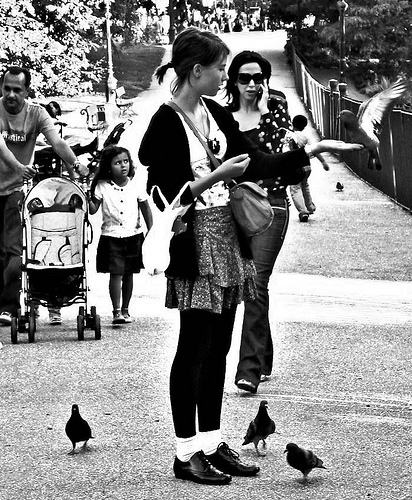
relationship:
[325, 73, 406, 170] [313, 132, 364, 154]
pigeon landing on hand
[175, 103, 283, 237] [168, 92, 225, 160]
purse has strap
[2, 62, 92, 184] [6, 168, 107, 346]
man pushing stroller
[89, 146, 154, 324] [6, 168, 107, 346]
girl walking next stroller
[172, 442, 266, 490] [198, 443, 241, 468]
shoes have black laces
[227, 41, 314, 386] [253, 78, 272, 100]
lady has cell pone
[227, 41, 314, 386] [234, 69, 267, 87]
lady wearing sunglasses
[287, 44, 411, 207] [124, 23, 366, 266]
fence runs along walkway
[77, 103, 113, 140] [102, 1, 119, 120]
bench next to post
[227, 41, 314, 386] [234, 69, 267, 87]
woman wearing sunglasses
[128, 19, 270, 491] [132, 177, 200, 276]
woman carrying bag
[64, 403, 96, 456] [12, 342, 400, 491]
birds on ground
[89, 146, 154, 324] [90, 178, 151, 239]
girl wearing shirt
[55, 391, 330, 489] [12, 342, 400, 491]
birds are on ground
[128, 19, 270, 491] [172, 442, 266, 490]
woman has black shoes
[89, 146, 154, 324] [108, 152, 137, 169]
girl looking away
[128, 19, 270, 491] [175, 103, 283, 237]
woman has a purse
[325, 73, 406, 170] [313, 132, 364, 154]
bird eating from hand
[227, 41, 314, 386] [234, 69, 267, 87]
woman has sunglasses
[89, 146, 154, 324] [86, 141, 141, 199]
girl has dark hair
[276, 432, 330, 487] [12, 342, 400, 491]
bird on ground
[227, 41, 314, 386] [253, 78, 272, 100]
woman holds cell phone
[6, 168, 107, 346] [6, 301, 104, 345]
stroller has dark wheels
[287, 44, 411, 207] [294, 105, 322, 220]
fence next to people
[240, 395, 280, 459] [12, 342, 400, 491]
pigeon on ground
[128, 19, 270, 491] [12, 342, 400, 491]
woman on pavement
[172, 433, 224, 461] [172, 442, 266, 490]
socks are on feet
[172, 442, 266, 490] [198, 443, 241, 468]
shoes has shoe laces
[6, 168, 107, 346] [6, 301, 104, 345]
stroller has wheels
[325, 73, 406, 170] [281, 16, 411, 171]
pigeon flying in air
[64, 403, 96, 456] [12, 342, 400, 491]
birds walking in street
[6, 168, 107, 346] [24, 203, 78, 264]
stroller foa a baby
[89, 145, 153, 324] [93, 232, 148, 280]
girl wearing skirt